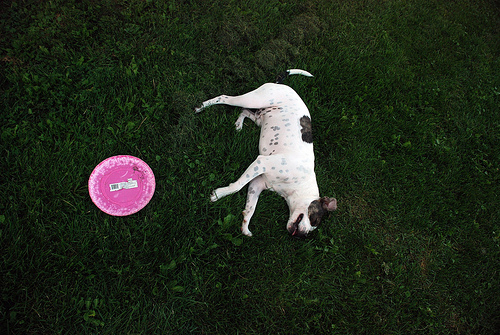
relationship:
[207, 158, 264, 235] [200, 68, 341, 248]
legs of dog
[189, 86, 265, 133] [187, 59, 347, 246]
legs of dogs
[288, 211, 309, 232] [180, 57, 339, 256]
mouth of dog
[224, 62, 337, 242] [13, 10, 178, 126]
dog lying in ground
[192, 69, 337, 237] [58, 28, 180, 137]
dog laying on grass